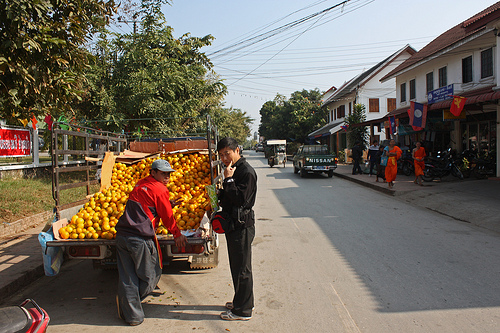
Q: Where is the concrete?
A: In the ground.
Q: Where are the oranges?
A: In the truck.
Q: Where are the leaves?
A: On the trees.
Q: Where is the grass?
A: On the ground.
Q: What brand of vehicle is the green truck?
A: Nissan.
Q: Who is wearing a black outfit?
A: The man at the first truck.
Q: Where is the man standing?
A: The pavement.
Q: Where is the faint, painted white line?
A: The road.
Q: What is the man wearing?
A: Black outfit.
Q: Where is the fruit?
A: In the back of the truck.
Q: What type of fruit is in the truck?
A: Oranges.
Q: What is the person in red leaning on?
A: Truck.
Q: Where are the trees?
A: On the side of the road.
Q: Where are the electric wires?
A: Overhead between the buildings.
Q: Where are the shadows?
A: On the ground.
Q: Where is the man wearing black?
A: By the truck.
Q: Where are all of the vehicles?
A: Parked by the side of the road.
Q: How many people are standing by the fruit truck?
A: Two.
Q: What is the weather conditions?
A: Sunny.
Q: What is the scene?
A: A small town.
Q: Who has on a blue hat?
A: The guy in the red jacket.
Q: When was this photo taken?
A: During the daytime.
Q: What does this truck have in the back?
A: Fruit.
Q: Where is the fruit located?
A: In the back of the truck.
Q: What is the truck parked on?
A: The street.